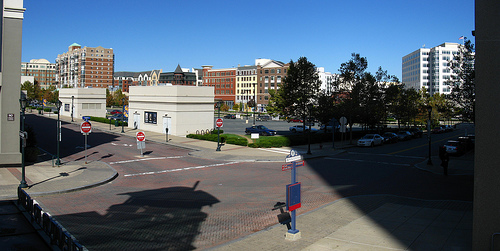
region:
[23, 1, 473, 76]
blue of daytime sky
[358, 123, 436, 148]
cars parked along street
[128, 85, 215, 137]
square plain gray building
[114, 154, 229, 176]
white lines on street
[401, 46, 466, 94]
windows on office building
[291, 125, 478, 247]
shadow of building over street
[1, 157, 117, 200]
corner of city intersection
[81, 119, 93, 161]
sign with red circle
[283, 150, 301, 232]
sign on blue pole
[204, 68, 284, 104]
windows on three buildings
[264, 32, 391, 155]
trees growing in the grass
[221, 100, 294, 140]
parking lot next to the buildings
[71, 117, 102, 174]
sign next to the building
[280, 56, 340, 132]
tree has green leaves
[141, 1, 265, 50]
the sky is clear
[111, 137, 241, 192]
lines painted on the road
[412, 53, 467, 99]
windows on the building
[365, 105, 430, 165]
cars parked in the road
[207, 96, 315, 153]
cars parked in the parking lot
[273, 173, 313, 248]
Blue and red pole on sidewalk.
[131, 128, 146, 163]
Red and white sign on road.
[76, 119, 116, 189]
Red and white sign on sidewalk.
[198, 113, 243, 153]
Red and white sign attached to pole.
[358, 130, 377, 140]
White car parked on side of street.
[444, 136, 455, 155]
White car parked on side of road.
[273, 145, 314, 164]
White sign attached to blue pole.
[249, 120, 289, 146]
Car parked in parking lot.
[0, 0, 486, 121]
Bright blue sky over a city.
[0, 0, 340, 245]
A city intersection.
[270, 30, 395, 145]
Trees in shadow against a vivid blue sky.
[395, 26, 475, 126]
A tall white building.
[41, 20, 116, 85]
A brick building against a blue sky.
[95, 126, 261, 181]
A crosswalk at an intersection.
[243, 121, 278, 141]
A parked car.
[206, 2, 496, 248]
Long shadows cover part of the street.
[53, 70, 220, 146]
Two buildings which look very similar.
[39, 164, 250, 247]
The shadow of a building towers over a road.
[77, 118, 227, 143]
Red traffic signs on road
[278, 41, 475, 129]
trees growing in city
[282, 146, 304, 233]
street sign on blue pole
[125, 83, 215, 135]
white office building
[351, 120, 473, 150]
cars parked on side of road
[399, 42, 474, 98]
tall white high rise building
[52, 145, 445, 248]
red brick street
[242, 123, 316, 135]
cars parked in parking lot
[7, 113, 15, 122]
sign on side of building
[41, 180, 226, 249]
shadow cast of building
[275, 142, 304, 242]
sign stands next to street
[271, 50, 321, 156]
tree next to street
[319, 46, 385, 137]
tree next to street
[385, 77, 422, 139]
tree next to street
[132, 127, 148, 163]
sign next to street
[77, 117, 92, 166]
sign next to street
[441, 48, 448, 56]
glass window on building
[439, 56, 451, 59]
glass window on building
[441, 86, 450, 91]
glass window on building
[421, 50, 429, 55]
glass window on building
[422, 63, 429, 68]
glass window on building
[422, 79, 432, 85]
glass window on building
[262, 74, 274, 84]
glass window on building